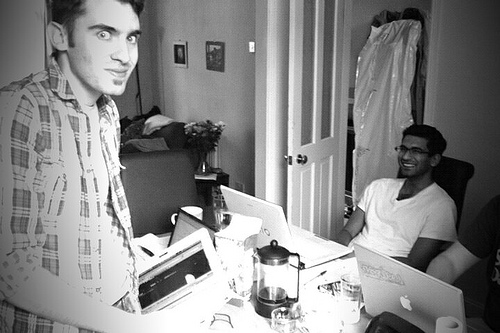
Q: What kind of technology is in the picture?
A: A laptop and an iPad.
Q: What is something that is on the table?
A: A lantern.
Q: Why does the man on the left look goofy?
A: His eyes are wide open.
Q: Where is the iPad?
A: In the man's hands.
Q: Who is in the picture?
A: Two men.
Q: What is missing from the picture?
A: Color.